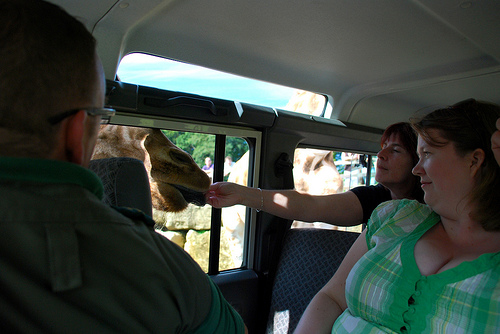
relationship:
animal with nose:
[91, 123, 212, 213] [172, 171, 239, 204]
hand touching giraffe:
[241, 174, 338, 218] [137, 142, 261, 212]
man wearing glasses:
[0, 0, 248, 334] [364, 127, 404, 171]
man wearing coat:
[0, 0, 248, 334] [307, 176, 410, 241]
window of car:
[104, 116, 267, 281] [164, 210, 251, 266]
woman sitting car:
[288, 97, 500, 334] [11, 23, 467, 330]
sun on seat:
[259, 310, 281, 330] [287, 232, 327, 282]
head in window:
[128, 113, 180, 202] [116, 81, 359, 331]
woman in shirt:
[288, 97, 500, 334] [364, 254, 447, 330]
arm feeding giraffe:
[233, 183, 341, 228] [139, 142, 205, 202]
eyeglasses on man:
[72, 104, 116, 132] [27, 59, 166, 270]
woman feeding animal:
[204, 121, 424, 228] [91, 123, 212, 213]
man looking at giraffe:
[0, 0, 248, 334] [134, 130, 232, 228]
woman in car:
[204, 121, 424, 228] [170, 49, 325, 210]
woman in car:
[204, 121, 424, 228] [148, 59, 318, 171]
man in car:
[0, 0, 248, 334] [202, 52, 346, 134]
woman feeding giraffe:
[242, 136, 413, 222] [119, 129, 201, 209]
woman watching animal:
[376, 127, 488, 317] [91, 123, 212, 213]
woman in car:
[376, 127, 488, 317] [251, 38, 396, 128]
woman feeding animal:
[204, 121, 424, 228] [151, 139, 229, 231]